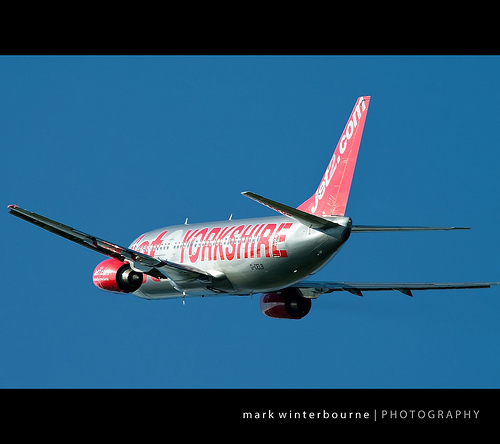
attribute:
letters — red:
[134, 220, 293, 264]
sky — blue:
[59, 90, 223, 169]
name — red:
[174, 221, 293, 259]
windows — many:
[142, 235, 257, 248]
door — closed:
[162, 240, 174, 251]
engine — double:
[91, 255, 314, 322]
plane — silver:
[106, 209, 356, 304]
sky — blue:
[35, 300, 200, 380]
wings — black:
[348, 220, 484, 301]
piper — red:
[90, 255, 145, 294]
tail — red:
[303, 95, 369, 215]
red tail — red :
[280, 85, 391, 235]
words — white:
[299, 88, 373, 231]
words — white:
[235, 402, 488, 424]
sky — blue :
[14, 76, 485, 376]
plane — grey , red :
[11, 90, 496, 332]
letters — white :
[239, 402, 495, 424]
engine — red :
[76, 248, 324, 335]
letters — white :
[308, 100, 376, 218]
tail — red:
[314, 87, 371, 229]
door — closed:
[269, 232, 279, 258]